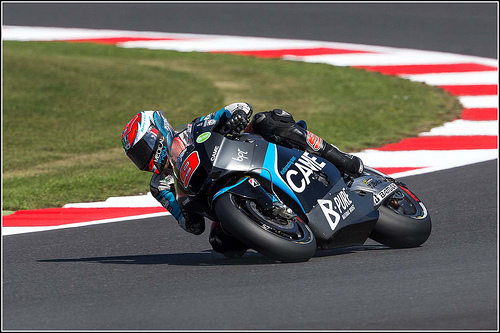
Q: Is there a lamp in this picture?
A: No, there are no lamps.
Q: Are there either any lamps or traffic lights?
A: No, there are no lamps or traffic lights.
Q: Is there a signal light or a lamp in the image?
A: No, there are no lamps or traffic lights.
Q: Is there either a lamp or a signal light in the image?
A: No, there are no lamps or traffic lights.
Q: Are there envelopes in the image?
A: No, there are no envelopes.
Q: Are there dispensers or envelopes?
A: No, there are no envelopes or dispensers.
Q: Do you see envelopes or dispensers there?
A: No, there are no envelopes or dispensers.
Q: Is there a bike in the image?
A: Yes, there is a bike.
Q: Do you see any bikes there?
A: Yes, there is a bike.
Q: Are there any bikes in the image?
A: Yes, there is a bike.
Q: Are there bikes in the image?
A: Yes, there is a bike.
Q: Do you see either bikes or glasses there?
A: Yes, there is a bike.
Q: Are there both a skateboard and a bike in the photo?
A: No, there is a bike but no skateboards.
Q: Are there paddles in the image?
A: No, there are no paddles.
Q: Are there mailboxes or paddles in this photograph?
A: No, there are no paddles or mailboxes.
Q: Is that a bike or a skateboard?
A: That is a bike.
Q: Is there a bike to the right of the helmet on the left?
A: Yes, there is a bike to the right of the helmet.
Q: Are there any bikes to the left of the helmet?
A: No, the bike is to the right of the helmet.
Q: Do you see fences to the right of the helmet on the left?
A: No, there is a bike to the right of the helmet.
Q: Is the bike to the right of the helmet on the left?
A: Yes, the bike is to the right of the helmet.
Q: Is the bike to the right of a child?
A: No, the bike is to the right of the helmet.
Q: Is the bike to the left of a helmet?
A: No, the bike is to the right of a helmet.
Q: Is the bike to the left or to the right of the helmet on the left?
A: The bike is to the right of the helmet.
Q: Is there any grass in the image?
A: Yes, there is grass.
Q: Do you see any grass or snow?
A: Yes, there is grass.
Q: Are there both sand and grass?
A: No, there is grass but no sand.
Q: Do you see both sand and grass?
A: No, there is grass but no sand.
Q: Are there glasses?
A: No, there are no glasses.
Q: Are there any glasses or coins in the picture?
A: No, there are no glasses or coins.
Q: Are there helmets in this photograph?
A: Yes, there is a helmet.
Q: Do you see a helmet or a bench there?
A: Yes, there is a helmet.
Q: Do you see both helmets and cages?
A: No, there is a helmet but no cages.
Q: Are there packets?
A: No, there are no packets.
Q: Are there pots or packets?
A: No, there are no packets or pots.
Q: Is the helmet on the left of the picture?
A: Yes, the helmet is on the left of the image.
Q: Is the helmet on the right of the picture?
A: No, the helmet is on the left of the image.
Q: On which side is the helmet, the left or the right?
A: The helmet is on the left of the image.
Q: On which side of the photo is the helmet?
A: The helmet is on the left of the image.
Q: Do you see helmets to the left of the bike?
A: Yes, there is a helmet to the left of the bike.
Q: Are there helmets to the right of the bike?
A: No, the helmet is to the left of the bike.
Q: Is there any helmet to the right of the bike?
A: No, the helmet is to the left of the bike.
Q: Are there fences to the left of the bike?
A: No, there is a helmet to the left of the bike.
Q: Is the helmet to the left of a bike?
A: Yes, the helmet is to the left of a bike.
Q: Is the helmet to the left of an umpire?
A: No, the helmet is to the left of a bike.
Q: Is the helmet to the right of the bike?
A: No, the helmet is to the left of the bike.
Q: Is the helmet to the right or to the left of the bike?
A: The helmet is to the left of the bike.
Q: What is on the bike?
A: The helmet is on the bike.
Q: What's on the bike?
A: The helmet is on the bike.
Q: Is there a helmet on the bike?
A: Yes, there is a helmet on the bike.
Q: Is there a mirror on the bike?
A: No, there is a helmet on the bike.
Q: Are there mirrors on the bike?
A: No, there is a helmet on the bike.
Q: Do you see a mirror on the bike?
A: No, there is a helmet on the bike.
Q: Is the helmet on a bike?
A: Yes, the helmet is on a bike.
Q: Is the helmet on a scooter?
A: No, the helmet is on a bike.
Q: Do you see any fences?
A: No, there are no fences.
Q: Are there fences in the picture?
A: No, there are no fences.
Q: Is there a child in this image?
A: No, there are no children.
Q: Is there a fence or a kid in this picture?
A: No, there are no children or fences.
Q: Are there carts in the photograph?
A: No, there are no carts.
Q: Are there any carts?
A: No, there are no carts.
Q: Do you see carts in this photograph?
A: No, there are no carts.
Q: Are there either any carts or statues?
A: No, there are no carts or statues.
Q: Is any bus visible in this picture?
A: No, there are no buses.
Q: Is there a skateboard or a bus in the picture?
A: No, there are no buses or skateboards.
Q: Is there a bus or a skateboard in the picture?
A: No, there are no buses or skateboards.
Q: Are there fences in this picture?
A: No, there are no fences.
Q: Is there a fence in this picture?
A: No, there are no fences.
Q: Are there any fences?
A: No, there are no fences.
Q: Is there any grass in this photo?
A: Yes, there is grass.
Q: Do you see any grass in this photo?
A: Yes, there is grass.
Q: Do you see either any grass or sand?
A: Yes, there is grass.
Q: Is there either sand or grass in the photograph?
A: Yes, there is grass.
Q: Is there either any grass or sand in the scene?
A: Yes, there is grass.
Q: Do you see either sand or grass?
A: Yes, there is grass.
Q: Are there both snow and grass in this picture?
A: No, there is grass but no snow.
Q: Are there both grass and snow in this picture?
A: No, there is grass but no snow.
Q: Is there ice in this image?
A: No, there is no ice.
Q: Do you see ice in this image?
A: No, there is no ice.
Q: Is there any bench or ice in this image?
A: No, there are no ice or benches.